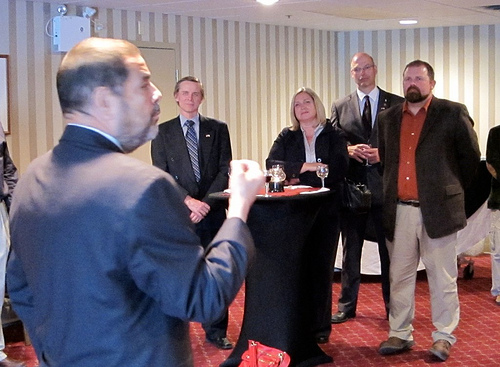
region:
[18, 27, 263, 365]
Guy in grey suit giving a speech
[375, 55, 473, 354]
Guy in brown blazer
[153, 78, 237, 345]
Man in black suit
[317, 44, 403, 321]
Tall bald man wearing a black tie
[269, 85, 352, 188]
Cute blond haired woman behind table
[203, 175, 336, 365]
Black island table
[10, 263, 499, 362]
Red carpet in conference room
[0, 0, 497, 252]
Brown Striped wall decoration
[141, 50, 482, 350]
Group paying attention to speaker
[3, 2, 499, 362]
Filled conference room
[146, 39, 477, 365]
people standing listening to speech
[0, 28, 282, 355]
man talking to audience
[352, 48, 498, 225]
man wearing brown shirt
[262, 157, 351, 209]
wine glasses on table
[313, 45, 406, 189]
man wearing white shirt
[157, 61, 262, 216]
man wearing suit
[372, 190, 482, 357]
man wearing beige pants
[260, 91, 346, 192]
lady wearing black jacket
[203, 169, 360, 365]
black round table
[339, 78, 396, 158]
man wearing black tie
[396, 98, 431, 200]
red dress shirt on the man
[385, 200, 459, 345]
khaki pants on the man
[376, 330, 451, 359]
brown shoes on the man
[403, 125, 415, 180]
white buttons on the red dress shirt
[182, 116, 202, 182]
blue and white striped tie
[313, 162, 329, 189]
empty wine glass near the woman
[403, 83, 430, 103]
dark beard on the man's face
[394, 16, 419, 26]
white light in the ceiling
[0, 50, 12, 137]
picture on the wall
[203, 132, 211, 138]
white pin on the man's black suit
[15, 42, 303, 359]
a man giving a speech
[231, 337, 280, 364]
red purse on the floor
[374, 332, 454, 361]
brown loafers on feet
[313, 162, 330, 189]
a wine glass on the table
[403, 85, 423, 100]
a dark brown beard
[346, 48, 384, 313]
a man holding a wine glass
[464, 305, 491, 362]
red patterned carpet on the floor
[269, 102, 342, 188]
a blond woman with folded arms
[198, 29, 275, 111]
white and tan stripes on the wall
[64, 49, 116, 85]
gray hair on a head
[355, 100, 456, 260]
man is wearing a coat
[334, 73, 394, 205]
man is wearing a coat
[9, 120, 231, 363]
man is wearing a coat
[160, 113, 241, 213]
man is wearing a coat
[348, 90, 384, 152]
man is wearing a tie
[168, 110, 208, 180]
man is wearing a tie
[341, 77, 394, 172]
man is wearing a tie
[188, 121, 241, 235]
man is wearing a tie